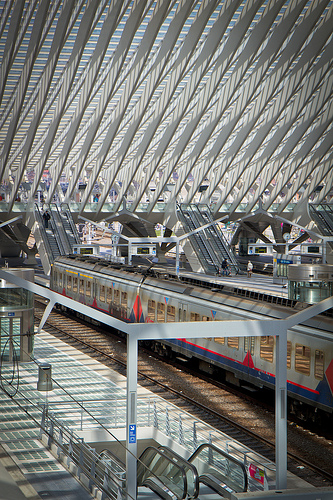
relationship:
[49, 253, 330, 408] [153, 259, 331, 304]
train has boarding area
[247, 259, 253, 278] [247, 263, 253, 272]
people in white dress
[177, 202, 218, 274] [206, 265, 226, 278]
escalator has base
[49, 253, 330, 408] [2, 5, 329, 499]
train at station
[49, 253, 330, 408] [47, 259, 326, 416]
train has cars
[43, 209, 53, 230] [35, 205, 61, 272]
person on escalator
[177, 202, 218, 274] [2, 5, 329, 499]
escalator in station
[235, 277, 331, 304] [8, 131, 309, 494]
boarding area at train station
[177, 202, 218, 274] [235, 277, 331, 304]
escalator at boarding area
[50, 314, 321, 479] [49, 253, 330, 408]
gravel next to train